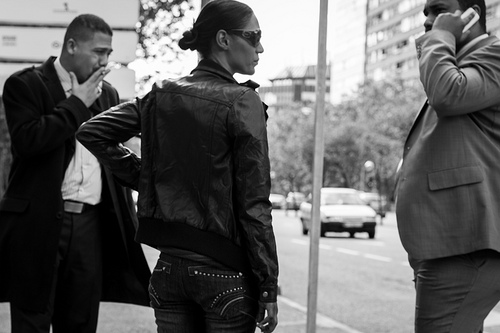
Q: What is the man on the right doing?
A: Talking on phone.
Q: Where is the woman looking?
A: Right.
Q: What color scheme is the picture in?
A: Black and white.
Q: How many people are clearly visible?
A: 3.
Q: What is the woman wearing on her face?
A: Sunglasses.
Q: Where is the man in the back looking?
A: Down.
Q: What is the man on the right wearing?
A: A suit.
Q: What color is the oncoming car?
A: White.